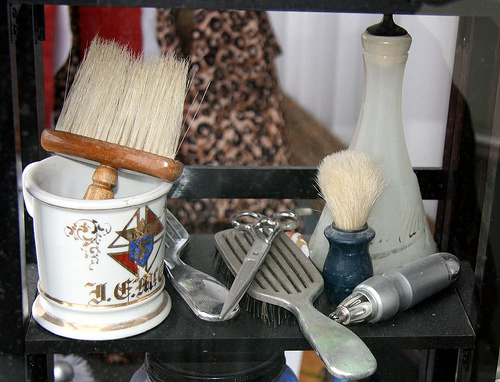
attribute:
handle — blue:
[322, 218, 377, 307]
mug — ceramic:
[18, 150, 186, 344]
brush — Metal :
[200, 213, 386, 380]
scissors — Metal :
[209, 203, 308, 325]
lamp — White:
[302, 13, 442, 292]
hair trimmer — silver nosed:
[331, 245, 461, 336]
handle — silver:
[292, 299, 384, 377]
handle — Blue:
[321, 220, 376, 297]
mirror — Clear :
[90, 0, 323, 186]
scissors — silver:
[116, 177, 353, 339]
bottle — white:
[306, 17, 439, 279]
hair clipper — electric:
[324, 249, 463, 324]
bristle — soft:
[264, 301, 271, 327]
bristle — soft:
[243, 293, 245, 312]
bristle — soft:
[250, 294, 255, 320]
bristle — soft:
[276, 307, 280, 327]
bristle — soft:
[208, 244, 216, 262]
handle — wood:
[80, 163, 118, 206]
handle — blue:
[320, 224, 377, 300]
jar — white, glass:
[300, 30, 437, 280]